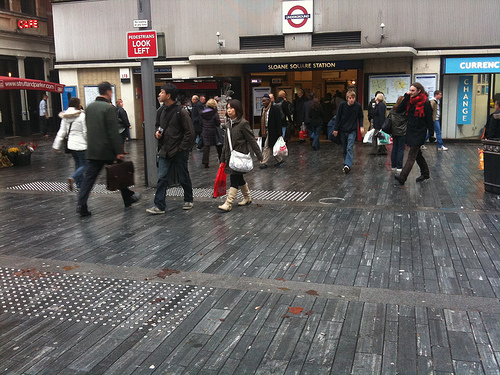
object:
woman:
[216, 98, 264, 212]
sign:
[456, 75, 473, 125]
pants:
[153, 151, 194, 212]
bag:
[212, 162, 227, 199]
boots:
[217, 182, 237, 211]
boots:
[238, 180, 254, 205]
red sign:
[127, 31, 157, 57]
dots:
[2, 309, 10, 314]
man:
[76, 81, 142, 217]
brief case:
[105, 160, 134, 191]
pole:
[137, 0, 161, 190]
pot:
[7, 141, 37, 167]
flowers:
[8, 147, 20, 153]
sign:
[17, 19, 39, 29]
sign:
[252, 86, 271, 116]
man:
[260, 93, 285, 169]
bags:
[272, 136, 288, 159]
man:
[332, 89, 365, 173]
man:
[145, 83, 197, 214]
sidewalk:
[0, 138, 499, 375]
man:
[420, 90, 449, 151]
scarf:
[405, 92, 428, 117]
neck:
[411, 93, 426, 100]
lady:
[51, 97, 88, 191]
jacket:
[52, 106, 88, 151]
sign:
[282, 1, 314, 34]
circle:
[285, 5, 310, 28]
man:
[393, 82, 436, 185]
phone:
[407, 90, 411, 96]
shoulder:
[239, 119, 251, 132]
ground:
[0, 133, 499, 374]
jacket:
[258, 101, 283, 149]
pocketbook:
[226, 127, 254, 173]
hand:
[117, 153, 125, 161]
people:
[105, 96, 135, 158]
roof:
[50, 1, 500, 74]